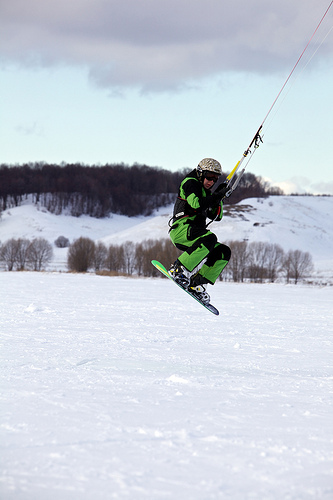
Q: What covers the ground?
A: Snow.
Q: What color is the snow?
A: White.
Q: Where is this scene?
A: Mountain.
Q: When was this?
A: Daytime.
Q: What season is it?
A: Winter.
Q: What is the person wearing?
A: A helmet.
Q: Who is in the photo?
A: A person.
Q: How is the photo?
A: Clear.